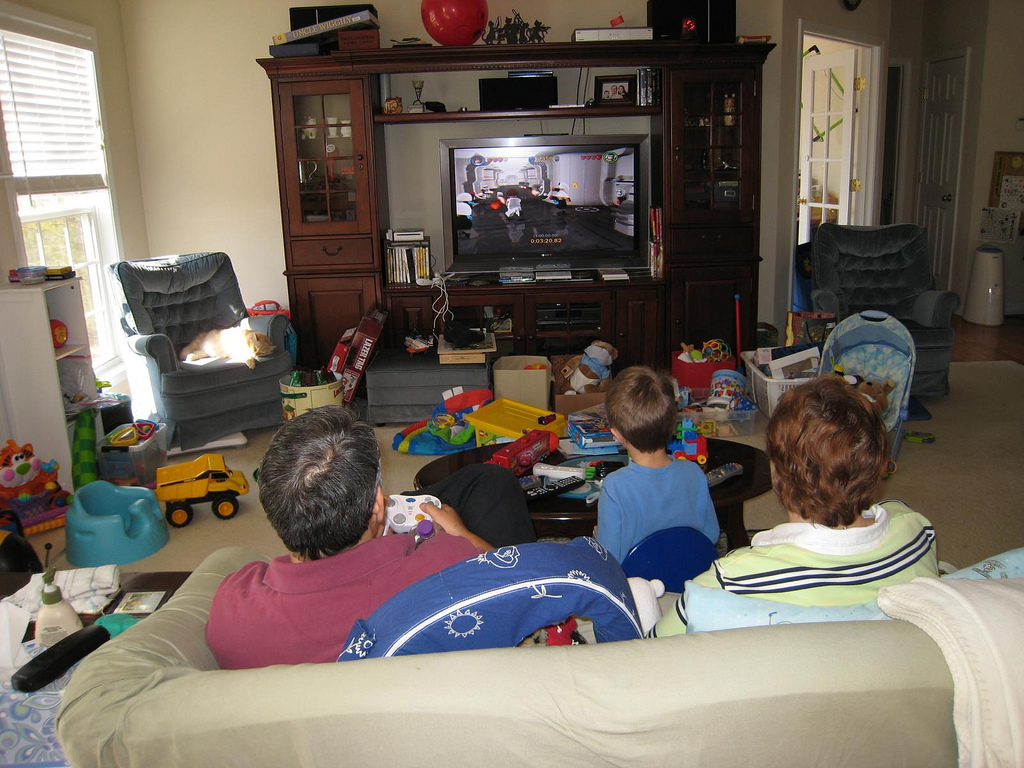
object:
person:
[643, 373, 939, 639]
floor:
[0, 307, 1024, 570]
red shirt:
[203, 534, 483, 670]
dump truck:
[153, 453, 251, 527]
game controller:
[383, 494, 441, 544]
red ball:
[421, 0, 489, 46]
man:
[203, 404, 535, 670]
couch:
[47, 545, 1021, 768]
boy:
[592, 364, 720, 565]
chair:
[619, 526, 721, 595]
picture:
[592, 74, 636, 107]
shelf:
[370, 106, 663, 125]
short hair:
[766, 375, 890, 529]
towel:
[0, 564, 120, 622]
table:
[0, 570, 192, 644]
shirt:
[595, 456, 719, 565]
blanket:
[876, 577, 1024, 765]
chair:
[65, 479, 171, 568]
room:
[0, 0, 1024, 768]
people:
[203, 365, 939, 670]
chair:
[810, 222, 961, 396]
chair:
[110, 250, 294, 451]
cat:
[180, 326, 278, 371]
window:
[797, 30, 884, 246]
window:
[0, 1, 128, 424]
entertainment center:
[440, 134, 650, 272]